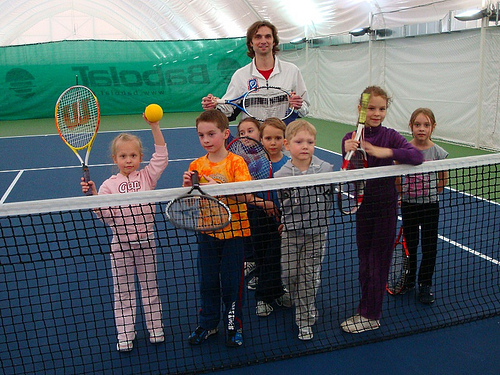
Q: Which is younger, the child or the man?
A: The child is younger than the man.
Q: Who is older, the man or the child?
A: The man is older than the child.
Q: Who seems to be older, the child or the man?
A: The man is older than the child.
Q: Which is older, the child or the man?
A: The man is older than the child.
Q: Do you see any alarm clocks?
A: No, there are no alarm clocks.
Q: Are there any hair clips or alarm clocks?
A: No, there are no alarm clocks or hair clips.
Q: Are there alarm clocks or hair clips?
A: No, there are no alarm clocks or hair clips.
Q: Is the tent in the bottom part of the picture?
A: No, the tent is in the top of the image.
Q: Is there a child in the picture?
A: Yes, there is a child.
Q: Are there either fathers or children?
A: Yes, there is a child.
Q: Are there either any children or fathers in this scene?
A: Yes, there is a child.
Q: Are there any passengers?
A: No, there are no passengers.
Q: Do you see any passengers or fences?
A: No, there are no passengers or fences.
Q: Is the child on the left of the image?
A: Yes, the child is on the left of the image.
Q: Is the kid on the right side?
A: No, the kid is on the left of the image.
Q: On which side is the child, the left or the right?
A: The child is on the left of the image.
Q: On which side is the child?
A: The child is on the left of the image.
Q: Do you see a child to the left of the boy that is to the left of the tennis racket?
A: Yes, there is a child to the left of the boy.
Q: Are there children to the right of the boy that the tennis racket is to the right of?
A: No, the child is to the left of the boy.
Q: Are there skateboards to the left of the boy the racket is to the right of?
A: No, there is a child to the left of the boy.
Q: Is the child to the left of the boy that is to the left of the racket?
A: Yes, the child is to the left of the boy.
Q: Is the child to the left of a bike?
A: No, the child is to the left of the boy.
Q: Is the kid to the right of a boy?
A: No, the kid is to the left of a boy.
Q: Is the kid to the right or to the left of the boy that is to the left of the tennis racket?
A: The kid is to the left of the boy.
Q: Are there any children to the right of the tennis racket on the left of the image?
A: Yes, there is a child to the right of the racket.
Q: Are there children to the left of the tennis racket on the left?
A: No, the child is to the right of the tennis racket.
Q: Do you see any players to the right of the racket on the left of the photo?
A: No, there is a child to the right of the tennis racket.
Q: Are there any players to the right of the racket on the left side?
A: No, there is a child to the right of the tennis racket.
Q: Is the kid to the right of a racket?
A: Yes, the kid is to the right of a racket.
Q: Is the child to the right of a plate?
A: No, the child is to the right of a racket.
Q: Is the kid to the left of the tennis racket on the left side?
A: No, the kid is to the right of the racket.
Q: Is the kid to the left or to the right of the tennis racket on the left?
A: The kid is to the right of the tennis racket.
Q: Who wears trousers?
A: The child wears trousers.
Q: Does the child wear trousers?
A: Yes, the child wears trousers.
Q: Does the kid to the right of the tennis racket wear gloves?
A: No, the child wears trousers.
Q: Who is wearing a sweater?
A: The kid is wearing a sweater.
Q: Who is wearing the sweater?
A: The kid is wearing a sweater.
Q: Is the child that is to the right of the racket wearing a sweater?
A: Yes, the kid is wearing a sweater.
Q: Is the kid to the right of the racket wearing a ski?
A: No, the child is wearing a sweater.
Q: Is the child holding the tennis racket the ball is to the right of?
A: Yes, the child is holding the racket.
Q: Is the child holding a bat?
A: No, the child is holding the racket.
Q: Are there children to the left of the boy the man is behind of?
A: Yes, there is a child to the left of the boy.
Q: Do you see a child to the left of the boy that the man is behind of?
A: Yes, there is a child to the left of the boy.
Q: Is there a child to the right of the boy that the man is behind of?
A: No, the child is to the left of the boy.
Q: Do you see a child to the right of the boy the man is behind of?
A: No, the child is to the left of the boy.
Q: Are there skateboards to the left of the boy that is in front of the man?
A: No, there is a child to the left of the boy.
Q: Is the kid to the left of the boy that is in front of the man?
A: Yes, the kid is to the left of the boy.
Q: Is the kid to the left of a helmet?
A: No, the kid is to the left of the boy.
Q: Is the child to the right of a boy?
A: No, the child is to the left of a boy.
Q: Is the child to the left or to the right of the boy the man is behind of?
A: The child is to the left of the boy.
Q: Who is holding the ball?
A: The kid is holding the ball.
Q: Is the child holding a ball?
A: Yes, the child is holding a ball.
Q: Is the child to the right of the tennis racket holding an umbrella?
A: No, the child is holding a ball.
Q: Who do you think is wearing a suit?
A: The kid is wearing a suit.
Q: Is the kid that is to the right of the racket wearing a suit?
A: Yes, the kid is wearing a suit.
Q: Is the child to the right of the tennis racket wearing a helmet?
A: No, the child is wearing a suit.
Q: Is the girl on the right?
A: Yes, the girl is on the right of the image.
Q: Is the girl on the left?
A: No, the girl is on the right of the image.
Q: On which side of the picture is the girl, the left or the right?
A: The girl is on the right of the image.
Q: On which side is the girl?
A: The girl is on the right of the image.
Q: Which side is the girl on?
A: The girl is on the right of the image.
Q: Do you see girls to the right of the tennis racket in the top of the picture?
A: Yes, there is a girl to the right of the tennis racket.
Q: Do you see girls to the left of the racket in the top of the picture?
A: No, the girl is to the right of the tennis racket.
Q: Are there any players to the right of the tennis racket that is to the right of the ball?
A: No, there is a girl to the right of the tennis racket.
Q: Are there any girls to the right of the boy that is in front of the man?
A: Yes, there is a girl to the right of the boy.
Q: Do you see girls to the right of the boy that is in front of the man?
A: Yes, there is a girl to the right of the boy.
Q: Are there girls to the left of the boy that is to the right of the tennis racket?
A: No, the girl is to the right of the boy.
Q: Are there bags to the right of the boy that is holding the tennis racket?
A: No, there is a girl to the right of the boy.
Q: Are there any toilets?
A: No, there are no toilets.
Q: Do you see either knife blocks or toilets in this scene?
A: No, there are no toilets or knife blocks.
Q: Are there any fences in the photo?
A: No, there are no fences.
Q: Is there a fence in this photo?
A: No, there are no fences.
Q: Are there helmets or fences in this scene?
A: No, there are no fences or helmets.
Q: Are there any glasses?
A: No, there are no glasses.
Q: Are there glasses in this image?
A: No, there are no glasses.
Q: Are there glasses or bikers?
A: No, there are no glasses or bikers.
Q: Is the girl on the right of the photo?
A: Yes, the girl is on the right of the image.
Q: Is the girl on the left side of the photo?
A: No, the girl is on the right of the image.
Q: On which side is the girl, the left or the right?
A: The girl is on the right of the image.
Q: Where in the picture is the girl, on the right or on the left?
A: The girl is on the right of the image.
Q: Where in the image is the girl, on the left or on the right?
A: The girl is on the right of the image.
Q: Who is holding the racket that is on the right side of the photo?
A: The girl is holding the racket.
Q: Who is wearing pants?
A: The girl is wearing pants.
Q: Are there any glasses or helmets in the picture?
A: No, there are no glasses or helmets.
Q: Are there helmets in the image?
A: No, there are no helmets.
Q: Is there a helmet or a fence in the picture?
A: No, there are no helmets or fences.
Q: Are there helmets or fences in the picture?
A: No, there are no helmets or fences.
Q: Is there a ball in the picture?
A: Yes, there is a ball.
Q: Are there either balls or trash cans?
A: Yes, there is a ball.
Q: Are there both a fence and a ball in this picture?
A: No, there is a ball but no fences.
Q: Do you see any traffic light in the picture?
A: No, there are no traffic lights.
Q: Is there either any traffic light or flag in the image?
A: No, there are no traffic lights or flags.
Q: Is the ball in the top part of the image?
A: Yes, the ball is in the top of the image.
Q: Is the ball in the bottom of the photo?
A: No, the ball is in the top of the image.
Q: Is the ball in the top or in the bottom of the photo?
A: The ball is in the top of the image.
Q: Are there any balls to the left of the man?
A: Yes, there is a ball to the left of the man.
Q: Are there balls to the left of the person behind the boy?
A: Yes, there is a ball to the left of the man.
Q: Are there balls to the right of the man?
A: No, the ball is to the left of the man.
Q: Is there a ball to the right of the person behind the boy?
A: No, the ball is to the left of the man.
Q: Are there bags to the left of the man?
A: No, there is a ball to the left of the man.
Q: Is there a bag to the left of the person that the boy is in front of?
A: No, there is a ball to the left of the man.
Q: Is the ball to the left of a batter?
A: No, the ball is to the left of the man.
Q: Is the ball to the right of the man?
A: No, the ball is to the left of the man.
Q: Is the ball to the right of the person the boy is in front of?
A: No, the ball is to the left of the man.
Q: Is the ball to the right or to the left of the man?
A: The ball is to the left of the man.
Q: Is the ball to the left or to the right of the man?
A: The ball is to the left of the man.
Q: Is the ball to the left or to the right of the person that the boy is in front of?
A: The ball is to the left of the man.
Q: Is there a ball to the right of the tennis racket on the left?
A: Yes, there is a ball to the right of the racket.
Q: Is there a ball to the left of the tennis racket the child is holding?
A: No, the ball is to the right of the tennis racket.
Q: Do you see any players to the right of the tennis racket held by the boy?
A: No, there is a ball to the right of the tennis racket.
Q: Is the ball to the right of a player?
A: No, the ball is to the right of a racket.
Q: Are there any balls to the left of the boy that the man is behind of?
A: Yes, there is a ball to the left of the boy.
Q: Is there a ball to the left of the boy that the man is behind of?
A: Yes, there is a ball to the left of the boy.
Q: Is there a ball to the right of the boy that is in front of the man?
A: No, the ball is to the left of the boy.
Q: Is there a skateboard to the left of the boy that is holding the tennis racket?
A: No, there is a ball to the left of the boy.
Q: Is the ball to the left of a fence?
A: No, the ball is to the left of the boy.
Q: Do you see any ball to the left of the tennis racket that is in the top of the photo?
A: Yes, there is a ball to the left of the tennis racket.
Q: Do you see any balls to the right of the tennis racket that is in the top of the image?
A: No, the ball is to the left of the racket.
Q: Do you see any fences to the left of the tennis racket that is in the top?
A: No, there is a ball to the left of the racket.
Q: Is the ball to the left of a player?
A: No, the ball is to the left of the tennis racket.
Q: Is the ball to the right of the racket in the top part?
A: No, the ball is to the left of the racket.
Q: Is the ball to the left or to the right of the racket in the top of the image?
A: The ball is to the left of the tennis racket.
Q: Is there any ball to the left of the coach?
A: Yes, there is a ball to the left of the coach.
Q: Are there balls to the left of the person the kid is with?
A: Yes, there is a ball to the left of the coach.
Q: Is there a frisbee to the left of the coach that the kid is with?
A: No, there is a ball to the left of the coach.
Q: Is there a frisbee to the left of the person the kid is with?
A: No, there is a ball to the left of the coach.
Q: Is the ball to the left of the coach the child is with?
A: Yes, the ball is to the left of the coach.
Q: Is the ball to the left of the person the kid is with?
A: Yes, the ball is to the left of the coach.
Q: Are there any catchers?
A: No, there are no catchers.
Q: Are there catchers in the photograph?
A: No, there are no catchers.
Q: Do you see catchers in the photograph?
A: No, there are no catchers.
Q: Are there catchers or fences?
A: No, there are no catchers or fences.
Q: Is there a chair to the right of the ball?
A: No, there is a coach to the right of the ball.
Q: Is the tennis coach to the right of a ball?
A: Yes, the coach is to the right of a ball.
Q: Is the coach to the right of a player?
A: No, the coach is to the right of a ball.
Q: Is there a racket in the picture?
A: Yes, there is a racket.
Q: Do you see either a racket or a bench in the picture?
A: Yes, there is a racket.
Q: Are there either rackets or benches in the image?
A: Yes, there is a racket.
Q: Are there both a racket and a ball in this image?
A: Yes, there are both a racket and a ball.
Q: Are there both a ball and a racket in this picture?
A: Yes, there are both a racket and a ball.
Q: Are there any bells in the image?
A: No, there are no bells.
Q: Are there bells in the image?
A: No, there are no bells.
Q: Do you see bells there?
A: No, there are no bells.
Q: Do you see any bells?
A: No, there are no bells.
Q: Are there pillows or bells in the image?
A: No, there are no bells or pillows.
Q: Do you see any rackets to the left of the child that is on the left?
A: Yes, there is a racket to the left of the child.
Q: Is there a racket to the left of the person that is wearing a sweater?
A: Yes, there is a racket to the left of the child.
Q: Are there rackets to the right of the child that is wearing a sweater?
A: No, the racket is to the left of the kid.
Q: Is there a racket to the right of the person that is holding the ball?
A: No, the racket is to the left of the kid.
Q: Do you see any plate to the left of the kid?
A: No, there is a racket to the left of the kid.